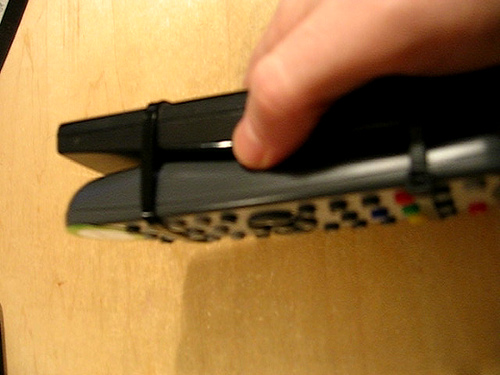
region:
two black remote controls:
[47, 51, 498, 226]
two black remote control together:
[40, 62, 498, 247]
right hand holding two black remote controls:
[230, 0, 498, 155]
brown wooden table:
[4, 1, 498, 369]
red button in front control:
[390, 190, 410, 205]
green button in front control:
[400, 205, 420, 215]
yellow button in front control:
[411, 215, 426, 235]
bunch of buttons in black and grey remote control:
[117, 177, 498, 247]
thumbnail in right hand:
[227, 118, 269, 168]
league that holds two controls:
[134, 94, 192, 259]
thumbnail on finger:
[223, 112, 283, 172]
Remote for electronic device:
[60, 130, 499, 264]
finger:
[224, 5, 364, 173]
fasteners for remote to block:
[138, 93, 170, 227]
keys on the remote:
[118, 185, 429, 249]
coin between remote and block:
[186, 125, 237, 159]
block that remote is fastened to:
[51, 83, 253, 176]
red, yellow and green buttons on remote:
[389, 175, 434, 222]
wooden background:
[27, 22, 209, 92]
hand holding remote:
[225, 1, 499, 171]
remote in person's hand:
[101, 89, 227, 259]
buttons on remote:
[309, 199, 368, 238]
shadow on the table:
[166, 266, 243, 326]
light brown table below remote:
[62, 268, 124, 303]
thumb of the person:
[228, 93, 320, 170]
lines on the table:
[26, 13, 106, 65]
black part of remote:
[182, 164, 229, 196]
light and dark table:
[115, 282, 262, 341]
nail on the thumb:
[220, 132, 254, 158]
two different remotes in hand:
[68, 68, 221, 288]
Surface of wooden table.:
[95, 245, 298, 362]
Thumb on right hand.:
[217, 32, 390, 199]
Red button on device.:
[385, 182, 441, 213]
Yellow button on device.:
[400, 210, 442, 240]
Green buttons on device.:
[393, 197, 435, 225]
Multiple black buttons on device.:
[197, 198, 421, 244]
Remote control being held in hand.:
[84, 105, 465, 258]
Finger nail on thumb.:
[205, 97, 319, 186]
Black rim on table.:
[1, 0, 45, 78]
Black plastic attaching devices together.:
[125, 90, 180, 249]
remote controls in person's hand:
[77, 79, 473, 271]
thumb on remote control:
[226, 61, 361, 161]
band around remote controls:
[106, 104, 198, 216]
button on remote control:
[325, 197, 353, 217]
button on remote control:
[398, 205, 418, 215]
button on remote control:
[410, 215, 424, 230]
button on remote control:
[370, 206, 389, 218]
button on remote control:
[300, 202, 322, 215]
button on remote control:
[217, 213, 238, 225]